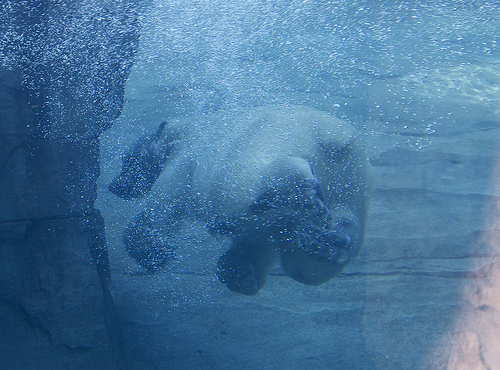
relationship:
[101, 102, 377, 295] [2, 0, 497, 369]
polar bear swimming in water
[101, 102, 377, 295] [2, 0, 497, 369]
polar bear under water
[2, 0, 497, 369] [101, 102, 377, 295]
water with polar bear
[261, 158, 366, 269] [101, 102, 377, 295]
legs of polar bear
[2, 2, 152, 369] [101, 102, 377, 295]
rock near polar bear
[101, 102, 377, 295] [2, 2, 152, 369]
polar bear near rock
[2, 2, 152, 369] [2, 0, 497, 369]
rock under water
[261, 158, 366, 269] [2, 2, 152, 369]
legs beside rock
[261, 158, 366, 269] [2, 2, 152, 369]
legs near rock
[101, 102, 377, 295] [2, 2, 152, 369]
polar bear close to rock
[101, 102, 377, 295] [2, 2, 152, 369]
polar bear next to rock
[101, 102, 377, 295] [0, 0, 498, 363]
polar bear making bubbles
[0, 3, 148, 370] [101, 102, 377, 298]
wall in front of polar bear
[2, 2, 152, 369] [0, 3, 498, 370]
rock in tank